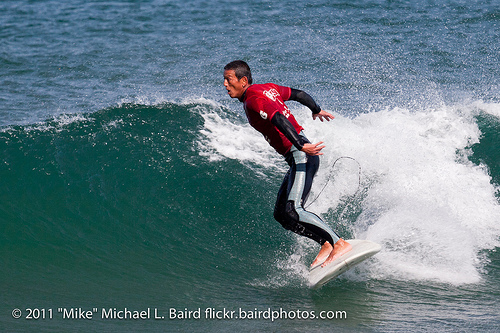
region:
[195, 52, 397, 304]
a man on a surf board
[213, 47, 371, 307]
a man riding a surf board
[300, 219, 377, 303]
a white surf board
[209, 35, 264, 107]
a man with black hair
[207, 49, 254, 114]
a man with short hair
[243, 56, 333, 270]
a man wearing a wet suit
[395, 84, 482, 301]
a white wave in the water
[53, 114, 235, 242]
a large wave in the ocean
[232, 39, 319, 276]
a man wearing a red, black and grey wetsuit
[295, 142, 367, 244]
a string attached to a surf board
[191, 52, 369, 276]
surfer wearing wet suit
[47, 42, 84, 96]
white and green waves in ocean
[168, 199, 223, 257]
white and green waves in ocean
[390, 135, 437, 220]
white and green waves in ocean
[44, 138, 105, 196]
white and green waves in ocean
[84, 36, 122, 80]
white and green waves in ocean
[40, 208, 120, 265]
white and green waves in ocean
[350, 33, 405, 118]
white and green waves in ocean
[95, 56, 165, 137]
white and green waves in ocean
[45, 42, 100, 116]
white and green waves in ocean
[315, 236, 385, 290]
a white surfboard riding a wave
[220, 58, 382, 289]
surfer on a surfboard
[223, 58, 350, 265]
man wearing black wetsuit with red shirt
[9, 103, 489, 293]
beautiful blue and white wave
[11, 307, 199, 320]
copywrite notice for Michael L Baird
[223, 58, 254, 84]
man has short black hair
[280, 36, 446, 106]
white spray from wave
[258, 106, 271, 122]
white design on red shirt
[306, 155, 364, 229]
surfboard to ankle retainer cord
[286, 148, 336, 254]
silver stripe down wetsuit leg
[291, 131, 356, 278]
This man has very lightweight pants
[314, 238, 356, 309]
There is a white surfboard on this photo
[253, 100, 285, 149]
There is a red shirt this man is wearing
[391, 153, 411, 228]
There is a very intense surf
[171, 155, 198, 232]
There is a light blue color in the water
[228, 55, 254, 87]
this man has a head full of brown hair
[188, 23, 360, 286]
Jackson Mingus took this photo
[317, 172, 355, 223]
There is a leash that is on this surfboard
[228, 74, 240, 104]
This man's face is rather red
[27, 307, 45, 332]
This photo was taken in 2001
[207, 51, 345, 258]
male surfer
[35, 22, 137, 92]
white and green waves in ocean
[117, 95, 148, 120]
white and green waves in ocean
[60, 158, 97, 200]
white and green waves in ocean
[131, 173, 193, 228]
white and green waves in ocean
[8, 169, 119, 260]
white and green waves in ocean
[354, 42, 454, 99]
white and green waves in ocean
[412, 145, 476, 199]
white and green waves in ocean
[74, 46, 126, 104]
white and green waves in ocean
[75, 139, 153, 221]
white and green waves in ocean